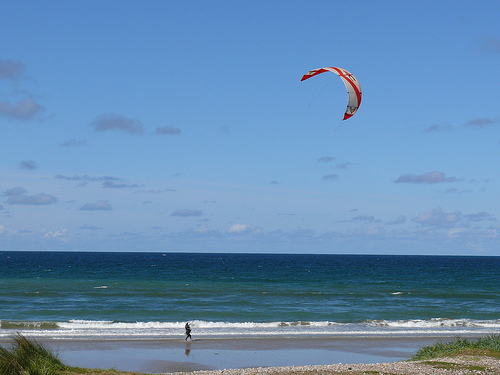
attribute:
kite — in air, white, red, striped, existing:
[299, 63, 364, 121]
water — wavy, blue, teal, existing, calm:
[0, 252, 499, 337]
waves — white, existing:
[0, 315, 499, 341]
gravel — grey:
[160, 353, 498, 375]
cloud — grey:
[151, 124, 183, 139]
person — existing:
[184, 318, 194, 343]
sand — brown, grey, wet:
[1, 336, 474, 375]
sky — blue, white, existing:
[1, 0, 499, 255]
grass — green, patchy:
[0, 331, 145, 374]